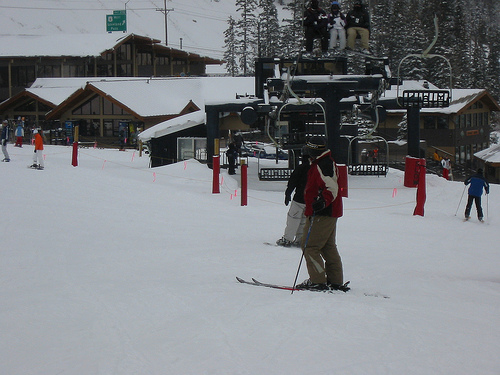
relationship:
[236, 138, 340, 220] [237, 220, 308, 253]
person on ski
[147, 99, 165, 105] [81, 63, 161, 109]
snow on roof